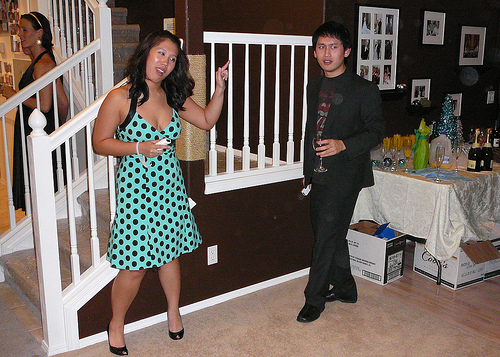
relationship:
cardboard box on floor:
[342, 218, 408, 286] [0, 237, 500, 354]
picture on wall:
[357, 5, 400, 90] [305, 5, 499, 147]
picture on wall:
[422, 10, 446, 45] [305, 5, 499, 147]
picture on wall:
[411, 78, 431, 105] [305, 5, 499, 147]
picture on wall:
[458, 25, 486, 65] [305, 5, 499, 147]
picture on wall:
[447, 92, 463, 116] [305, 5, 499, 147]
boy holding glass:
[296, 21, 386, 323] [295, 120, 353, 171]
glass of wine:
[295, 120, 353, 171] [314, 134, 323, 152]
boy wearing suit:
[296, 21, 386, 323] [298, 66, 385, 327]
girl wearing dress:
[91, 29, 230, 356] [106, 82, 203, 272]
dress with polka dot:
[106, 82, 203, 272] [170, 236, 176, 241]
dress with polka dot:
[106, 82, 203, 272] [171, 201, 176, 206]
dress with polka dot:
[106, 82, 203, 272] [134, 177, 141, 184]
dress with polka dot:
[106, 82, 203, 272] [126, 222, 130, 230]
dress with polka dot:
[106, 82, 203, 272] [169, 126, 175, 131]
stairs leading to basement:
[29, 9, 282, 282] [27, 86, 497, 326]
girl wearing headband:
[0, 11, 69, 216] [11, 0, 63, 25]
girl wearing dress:
[58, 26, 213, 347] [118, 90, 189, 236]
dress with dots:
[105, 84, 203, 270] [138, 177, 177, 227]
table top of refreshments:
[373, 151, 489, 199] [384, 127, 474, 165]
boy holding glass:
[296, 21, 386, 323] [305, 129, 330, 177]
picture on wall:
[448, 90, 465, 116] [401, 47, 443, 77]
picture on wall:
[455, 20, 486, 68] [401, 47, 443, 77]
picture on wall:
[422, 10, 446, 45] [401, 47, 443, 77]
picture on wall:
[352, 5, 404, 94] [401, 47, 443, 77]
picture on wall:
[406, 72, 432, 102] [401, 47, 443, 77]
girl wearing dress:
[91, 29, 230, 356] [89, 100, 216, 260]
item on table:
[466, 126, 492, 171] [349, 146, 496, 283]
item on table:
[436, 92, 462, 147] [349, 146, 496, 283]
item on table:
[432, 145, 446, 182] [349, 146, 496, 283]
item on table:
[413, 117, 454, 169] [349, 146, 496, 283]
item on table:
[370, 131, 415, 172] [349, 146, 496, 283]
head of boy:
[311, 23, 353, 72] [295, 22, 387, 321]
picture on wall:
[420, 7, 450, 52] [322, 3, 497, 131]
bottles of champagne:
[440, 130, 495, 181] [470, 124, 490, 174]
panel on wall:
[203, 241, 219, 267] [152, 181, 442, 296]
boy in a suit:
[296, 21, 386, 323] [303, 66, 384, 308]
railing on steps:
[18, 106, 140, 313] [56, 168, 114, 254]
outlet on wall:
[195, 219, 227, 293] [222, 199, 299, 267]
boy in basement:
[296, 21, 386, 323] [0, 1, 483, 355]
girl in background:
[5, 11, 73, 153] [0, 2, 103, 236]